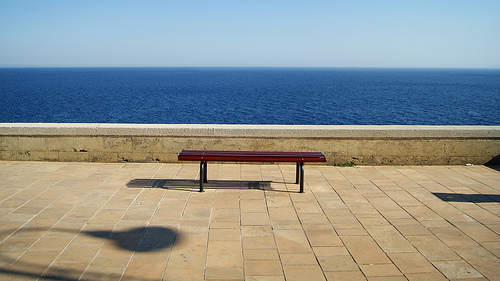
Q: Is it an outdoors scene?
A: Yes, it is outdoors.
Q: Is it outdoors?
A: Yes, it is outdoors.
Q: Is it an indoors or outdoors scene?
A: It is outdoors.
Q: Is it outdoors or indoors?
A: It is outdoors.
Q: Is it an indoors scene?
A: No, it is outdoors.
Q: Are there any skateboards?
A: No, there are no skateboards.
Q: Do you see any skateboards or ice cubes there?
A: No, there are no skateboards or ice cubes.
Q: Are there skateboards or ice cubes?
A: No, there are no skateboards or ice cubes.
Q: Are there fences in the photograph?
A: No, there are no fences.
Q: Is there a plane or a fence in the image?
A: No, there are no fences or airplanes.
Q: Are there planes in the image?
A: No, there are no planes.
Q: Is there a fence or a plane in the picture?
A: No, there are no airplanes or fences.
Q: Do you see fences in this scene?
A: No, there are no fences.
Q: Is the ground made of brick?
A: Yes, the ground is made of brick.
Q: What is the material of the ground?
A: The ground is made of brick.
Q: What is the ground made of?
A: The ground is made of brick.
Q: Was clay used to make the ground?
A: No, the ground is made of brick.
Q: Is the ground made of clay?
A: No, the ground is made of brick.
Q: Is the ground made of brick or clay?
A: The ground is made of brick.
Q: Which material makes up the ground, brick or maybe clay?
A: The ground is made of brick.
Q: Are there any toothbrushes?
A: No, there are no toothbrushes.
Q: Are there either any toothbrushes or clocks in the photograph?
A: No, there are no toothbrushes or clocks.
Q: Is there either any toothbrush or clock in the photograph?
A: No, there are no toothbrushes or clocks.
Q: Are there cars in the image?
A: No, there are no cars.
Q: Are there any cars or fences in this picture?
A: No, there are no cars or fences.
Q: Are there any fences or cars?
A: No, there are no cars or fences.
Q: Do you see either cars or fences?
A: No, there are no cars or fences.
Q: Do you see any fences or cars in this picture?
A: No, there are no cars or fences.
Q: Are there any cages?
A: No, there are no cages.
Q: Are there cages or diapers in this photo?
A: No, there are no cages or diapers.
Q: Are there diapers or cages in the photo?
A: No, there are no cages or diapers.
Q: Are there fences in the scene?
A: No, there are no fences.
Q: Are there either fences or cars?
A: No, there are no fences or cars.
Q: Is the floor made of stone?
A: Yes, the floor is made of stone.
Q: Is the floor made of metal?
A: No, the floor is made of stone.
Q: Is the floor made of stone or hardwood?
A: The floor is made of stone.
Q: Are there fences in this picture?
A: No, there are no fences.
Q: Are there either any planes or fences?
A: No, there are no fences or planes.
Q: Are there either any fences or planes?
A: No, there are no fences or planes.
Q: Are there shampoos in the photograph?
A: No, there are no shampoos.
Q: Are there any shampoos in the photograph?
A: No, there are no shampoos.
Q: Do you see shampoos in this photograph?
A: No, there are no shampoos.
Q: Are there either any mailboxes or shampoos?
A: No, there are no shampoos or mailboxes.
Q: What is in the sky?
A: The clouds are in the sky.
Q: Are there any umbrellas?
A: No, there are no umbrellas.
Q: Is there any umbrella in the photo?
A: No, there are no umbrellas.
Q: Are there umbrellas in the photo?
A: No, there are no umbrellas.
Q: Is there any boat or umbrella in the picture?
A: No, there are no umbrellas or boats.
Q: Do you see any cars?
A: No, there are no cars.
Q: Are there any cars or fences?
A: No, there are no cars or fences.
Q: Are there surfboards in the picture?
A: No, there are no surfboards.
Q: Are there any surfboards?
A: No, there are no surfboards.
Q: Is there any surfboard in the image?
A: No, there are no surfboards.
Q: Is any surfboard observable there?
A: No, there are no surfboards.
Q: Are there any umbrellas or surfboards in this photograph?
A: No, there are no surfboards or umbrellas.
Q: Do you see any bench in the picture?
A: Yes, there is a bench.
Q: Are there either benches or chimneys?
A: Yes, there is a bench.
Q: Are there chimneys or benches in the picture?
A: Yes, there is a bench.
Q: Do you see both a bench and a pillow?
A: No, there is a bench but no pillows.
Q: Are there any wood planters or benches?
A: Yes, there is a wood bench.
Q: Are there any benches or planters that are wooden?
A: Yes, the bench is wooden.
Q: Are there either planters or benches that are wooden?
A: Yes, the bench is wooden.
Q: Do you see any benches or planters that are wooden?
A: Yes, the bench is wooden.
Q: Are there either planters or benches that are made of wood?
A: Yes, the bench is made of wood.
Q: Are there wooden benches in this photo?
A: Yes, there is a wood bench.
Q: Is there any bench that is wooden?
A: Yes, there is a bench that is wooden.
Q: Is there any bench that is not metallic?
A: Yes, there is a wooden bench.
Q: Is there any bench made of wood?
A: Yes, there is a bench that is made of wood.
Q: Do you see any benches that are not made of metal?
A: Yes, there is a bench that is made of wood.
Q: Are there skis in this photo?
A: No, there are no skis.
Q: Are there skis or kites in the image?
A: No, there are no skis or kites.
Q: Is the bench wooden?
A: Yes, the bench is wooden.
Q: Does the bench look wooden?
A: Yes, the bench is wooden.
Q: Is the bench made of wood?
A: Yes, the bench is made of wood.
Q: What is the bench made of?
A: The bench is made of wood.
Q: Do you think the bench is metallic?
A: No, the bench is wooden.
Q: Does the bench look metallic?
A: No, the bench is wooden.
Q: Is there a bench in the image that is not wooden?
A: No, there is a bench but it is wooden.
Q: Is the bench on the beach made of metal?
A: No, the bench is made of wood.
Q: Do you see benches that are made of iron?
A: No, there is a bench but it is made of wood.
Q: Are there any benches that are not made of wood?
A: No, there is a bench but it is made of wood.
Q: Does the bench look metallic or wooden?
A: The bench is wooden.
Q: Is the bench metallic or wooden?
A: The bench is wooden.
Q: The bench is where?
A: The bench is on the beach.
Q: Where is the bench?
A: The bench is on the beach.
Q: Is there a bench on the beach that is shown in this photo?
A: Yes, there is a bench on the beach.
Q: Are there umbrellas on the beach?
A: No, there is a bench on the beach.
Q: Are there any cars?
A: No, there are no cars.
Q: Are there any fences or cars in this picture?
A: No, there are no cars or fences.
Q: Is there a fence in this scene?
A: No, there are no fences.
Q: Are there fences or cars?
A: No, there are no fences or cars.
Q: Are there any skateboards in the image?
A: No, there are no skateboards.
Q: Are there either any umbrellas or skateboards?
A: No, there are no skateboards or umbrellas.